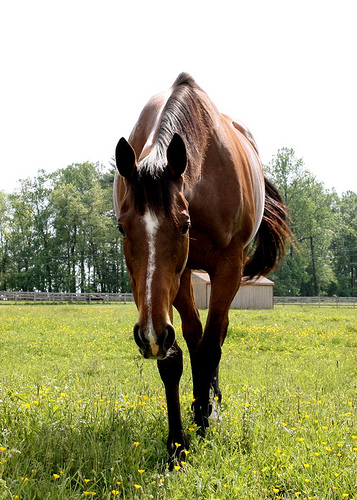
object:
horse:
[110, 70, 287, 441]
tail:
[242, 175, 302, 288]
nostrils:
[165, 325, 175, 351]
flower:
[137, 460, 160, 469]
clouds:
[0, 0, 354, 71]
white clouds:
[269, 44, 338, 97]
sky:
[0, 0, 356, 216]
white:
[137, 208, 159, 306]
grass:
[231, 313, 355, 497]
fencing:
[0, 290, 134, 302]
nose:
[132, 307, 177, 362]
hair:
[242, 171, 294, 286]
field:
[3, 314, 137, 497]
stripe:
[138, 210, 163, 353]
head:
[115, 130, 192, 360]